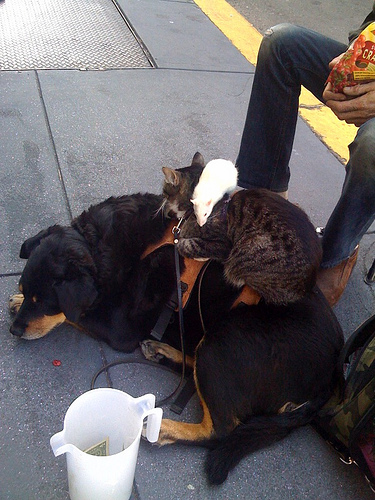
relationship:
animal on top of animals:
[153, 141, 326, 312] [4, 190, 359, 468]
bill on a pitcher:
[83, 428, 110, 458] [41, 379, 160, 490]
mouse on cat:
[184, 149, 243, 229] [148, 142, 326, 311]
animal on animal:
[153, 141, 326, 312] [8, 189, 349, 486]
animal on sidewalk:
[8, 189, 349, 486] [2, 3, 372, 497]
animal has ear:
[3, 178, 358, 497] [51, 269, 105, 328]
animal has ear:
[3, 178, 358, 497] [30, 232, 73, 279]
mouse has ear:
[190, 155, 243, 226] [186, 195, 198, 207]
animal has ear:
[153, 141, 326, 312] [157, 157, 182, 189]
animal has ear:
[153, 141, 341, 321] [187, 146, 203, 167]